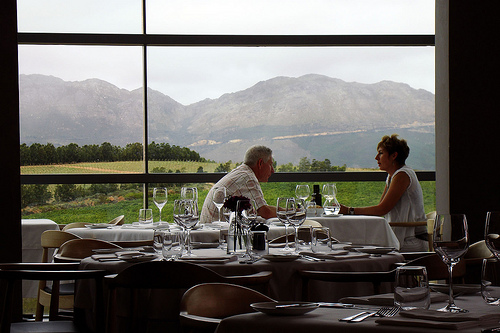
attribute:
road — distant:
[185, 122, 431, 148]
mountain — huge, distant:
[189, 74, 437, 168]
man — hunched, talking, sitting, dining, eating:
[200, 145, 275, 219]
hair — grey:
[243, 145, 271, 162]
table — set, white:
[308, 216, 402, 251]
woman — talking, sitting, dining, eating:
[346, 134, 429, 250]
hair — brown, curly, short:
[379, 134, 410, 169]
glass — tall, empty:
[297, 186, 312, 209]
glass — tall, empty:
[323, 183, 336, 197]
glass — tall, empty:
[152, 187, 167, 226]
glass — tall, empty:
[180, 185, 196, 203]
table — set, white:
[69, 221, 229, 244]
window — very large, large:
[15, 0, 435, 316]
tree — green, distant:
[43, 144, 56, 163]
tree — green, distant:
[65, 145, 76, 163]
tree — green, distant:
[100, 142, 113, 162]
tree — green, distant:
[126, 143, 143, 162]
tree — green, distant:
[149, 143, 158, 160]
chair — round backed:
[33, 231, 81, 321]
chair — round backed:
[52, 240, 120, 323]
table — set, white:
[81, 242, 407, 295]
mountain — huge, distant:
[133, 85, 182, 106]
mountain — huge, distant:
[18, 74, 127, 146]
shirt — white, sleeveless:
[385, 169, 423, 244]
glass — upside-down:
[139, 209, 153, 225]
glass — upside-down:
[310, 226, 330, 252]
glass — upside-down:
[391, 263, 433, 310]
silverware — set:
[323, 302, 403, 332]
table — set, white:
[213, 284, 496, 333]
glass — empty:
[434, 215, 468, 312]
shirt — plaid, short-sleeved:
[200, 164, 270, 226]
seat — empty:
[184, 280, 270, 332]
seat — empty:
[104, 261, 269, 329]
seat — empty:
[299, 248, 467, 290]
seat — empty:
[58, 239, 116, 312]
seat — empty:
[6, 257, 101, 333]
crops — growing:
[23, 161, 224, 177]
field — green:
[22, 158, 213, 188]